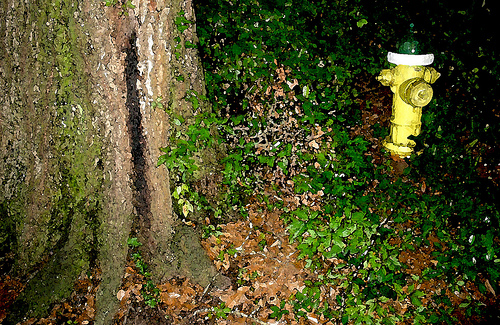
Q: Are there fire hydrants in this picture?
A: Yes, there is a fire hydrant.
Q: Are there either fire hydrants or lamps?
A: Yes, there is a fire hydrant.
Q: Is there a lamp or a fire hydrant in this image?
A: Yes, there is a fire hydrant.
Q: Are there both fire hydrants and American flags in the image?
A: No, there is a fire hydrant but no American flags.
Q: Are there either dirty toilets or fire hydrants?
A: Yes, there is a dirty fire hydrant.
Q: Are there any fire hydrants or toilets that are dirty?
A: Yes, the fire hydrant is dirty.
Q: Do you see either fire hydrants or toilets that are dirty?
A: Yes, the fire hydrant is dirty.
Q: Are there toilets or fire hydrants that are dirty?
A: Yes, the fire hydrant is dirty.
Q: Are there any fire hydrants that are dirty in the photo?
A: Yes, there is a dirty fire hydrant.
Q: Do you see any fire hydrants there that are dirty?
A: Yes, there is a fire hydrant that is dirty.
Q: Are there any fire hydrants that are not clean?
A: Yes, there is a dirty fire hydrant.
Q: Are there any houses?
A: No, there are no houses.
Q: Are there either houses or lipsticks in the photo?
A: No, there are no houses or lipsticks.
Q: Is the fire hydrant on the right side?
A: Yes, the fire hydrant is on the right of the image.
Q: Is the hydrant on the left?
A: No, the hydrant is on the right of the image.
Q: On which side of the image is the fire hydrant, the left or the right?
A: The fire hydrant is on the right of the image.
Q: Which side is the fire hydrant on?
A: The fire hydrant is on the right of the image.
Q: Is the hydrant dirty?
A: Yes, the hydrant is dirty.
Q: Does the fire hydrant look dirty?
A: Yes, the fire hydrant is dirty.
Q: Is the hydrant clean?
A: No, the hydrant is dirty.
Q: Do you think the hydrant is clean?
A: No, the hydrant is dirty.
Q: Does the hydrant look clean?
A: No, the hydrant is dirty.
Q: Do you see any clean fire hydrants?
A: No, there is a fire hydrant but it is dirty.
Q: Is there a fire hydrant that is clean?
A: No, there is a fire hydrant but it is dirty.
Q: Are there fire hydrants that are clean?
A: No, there is a fire hydrant but it is dirty.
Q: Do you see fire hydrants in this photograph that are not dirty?
A: No, there is a fire hydrant but it is dirty.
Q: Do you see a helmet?
A: No, there are no helmets.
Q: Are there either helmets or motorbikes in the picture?
A: No, there are no helmets or motorbikes.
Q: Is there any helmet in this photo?
A: No, there are no helmets.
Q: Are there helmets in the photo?
A: No, there are no helmets.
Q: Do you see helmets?
A: No, there are no helmets.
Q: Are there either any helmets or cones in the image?
A: No, there are no helmets or cones.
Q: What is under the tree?
A: The dirt is under the tree.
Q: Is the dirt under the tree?
A: Yes, the dirt is under the tree.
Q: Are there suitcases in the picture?
A: No, there are no suitcases.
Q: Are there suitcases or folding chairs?
A: No, there are no suitcases or folding chairs.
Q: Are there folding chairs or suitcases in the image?
A: No, there are no suitcases or folding chairs.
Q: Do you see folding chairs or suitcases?
A: No, there are no suitcases or folding chairs.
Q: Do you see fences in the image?
A: No, there are no fences.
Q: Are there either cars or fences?
A: No, there are no fences or cars.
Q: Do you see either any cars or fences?
A: No, there are no fences or cars.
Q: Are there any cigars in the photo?
A: No, there are no cigars.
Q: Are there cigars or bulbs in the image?
A: No, there are no cigars or bulbs.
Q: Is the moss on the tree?
A: Yes, the moss is on the tree.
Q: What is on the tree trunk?
A: The moss is on the trunk.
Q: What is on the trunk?
A: The moss is on the trunk.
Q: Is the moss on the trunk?
A: Yes, the moss is on the trunk.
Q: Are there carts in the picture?
A: No, there are no carts.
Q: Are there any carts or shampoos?
A: No, there are no carts or shampoos.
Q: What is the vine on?
A: The vine is on the tree.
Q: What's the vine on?
A: The vine is on the tree.